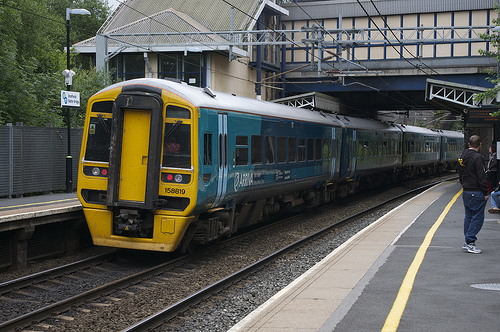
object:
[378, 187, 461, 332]
line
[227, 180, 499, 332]
pavement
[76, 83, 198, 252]
yellow front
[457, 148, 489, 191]
jacket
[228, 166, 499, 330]
platform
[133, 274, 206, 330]
gravel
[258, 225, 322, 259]
tracks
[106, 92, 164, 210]
door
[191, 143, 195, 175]
edge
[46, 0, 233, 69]
cords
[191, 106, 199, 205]
train edge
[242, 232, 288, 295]
gravel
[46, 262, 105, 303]
tracks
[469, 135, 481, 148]
hair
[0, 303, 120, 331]
train tracks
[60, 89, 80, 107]
sign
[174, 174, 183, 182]
lights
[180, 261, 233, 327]
tracks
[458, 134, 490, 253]
man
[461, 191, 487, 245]
pants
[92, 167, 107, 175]
headlights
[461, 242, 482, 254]
shoe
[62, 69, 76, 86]
box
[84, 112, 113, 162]
windshield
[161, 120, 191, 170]
windshield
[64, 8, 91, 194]
lamp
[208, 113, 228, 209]
door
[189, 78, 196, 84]
white sign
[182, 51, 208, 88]
window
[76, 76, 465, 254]
front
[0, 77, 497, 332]
station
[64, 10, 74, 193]
pole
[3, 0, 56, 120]
trees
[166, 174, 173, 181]
lights